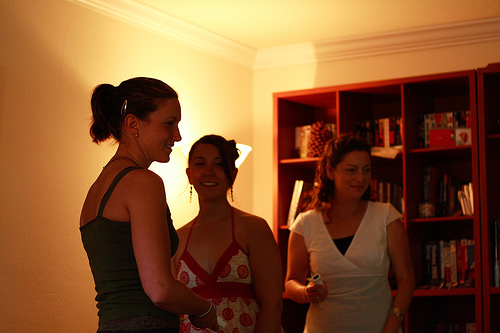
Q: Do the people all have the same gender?
A: Yes, all the people are female.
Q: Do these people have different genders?
A: No, all the people are female.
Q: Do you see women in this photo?
A: Yes, there are women.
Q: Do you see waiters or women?
A: Yes, there are women.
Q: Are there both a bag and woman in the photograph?
A: No, there are women but no bags.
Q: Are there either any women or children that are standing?
A: Yes, the women are standing.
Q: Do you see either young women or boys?
A: Yes, there are young women.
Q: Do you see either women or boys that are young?
A: Yes, the women are young.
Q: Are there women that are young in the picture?
A: Yes, there are young women.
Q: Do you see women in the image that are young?
A: Yes, there are women that are young.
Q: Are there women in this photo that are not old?
A: Yes, there are young women.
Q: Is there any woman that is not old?
A: Yes, there are young women.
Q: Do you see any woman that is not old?
A: Yes, there are young women.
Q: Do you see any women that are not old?
A: Yes, there are young women.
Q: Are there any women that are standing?
A: Yes, there are women that are standing.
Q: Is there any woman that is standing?
A: Yes, there are women that are standing.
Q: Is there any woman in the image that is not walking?
A: Yes, there are women that are standing.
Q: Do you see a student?
A: No, there are no students.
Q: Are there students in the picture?
A: No, there are no students.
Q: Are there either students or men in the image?
A: No, there are no students or men.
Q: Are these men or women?
A: These are women.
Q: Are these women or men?
A: These are women.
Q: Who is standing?
A: The women are standing.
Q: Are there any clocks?
A: No, there are no clocks.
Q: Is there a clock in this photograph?
A: No, there are no clocks.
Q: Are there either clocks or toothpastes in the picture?
A: No, there are no clocks or toothpastes.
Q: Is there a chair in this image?
A: No, there are no chairs.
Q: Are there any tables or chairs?
A: No, there are no chairs or tables.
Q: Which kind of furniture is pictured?
A: The furniture is a shelf.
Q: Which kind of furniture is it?
A: The piece of furniture is a shelf.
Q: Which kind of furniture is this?
A: This is a shelf.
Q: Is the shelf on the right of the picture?
A: Yes, the shelf is on the right of the image.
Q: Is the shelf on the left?
A: No, the shelf is on the right of the image.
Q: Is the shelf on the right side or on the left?
A: The shelf is on the right of the image.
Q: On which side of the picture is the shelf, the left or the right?
A: The shelf is on the right of the image.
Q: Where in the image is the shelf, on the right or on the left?
A: The shelf is on the right of the image.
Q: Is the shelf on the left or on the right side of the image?
A: The shelf is on the right of the image.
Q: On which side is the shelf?
A: The shelf is on the right of the image.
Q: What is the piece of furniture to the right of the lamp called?
A: The piece of furniture is a shelf.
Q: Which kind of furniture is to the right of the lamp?
A: The piece of furniture is a shelf.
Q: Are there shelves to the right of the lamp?
A: Yes, there is a shelf to the right of the lamp.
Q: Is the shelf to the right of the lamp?
A: Yes, the shelf is to the right of the lamp.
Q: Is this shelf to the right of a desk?
A: No, the shelf is to the right of the lamp.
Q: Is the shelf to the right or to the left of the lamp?
A: The shelf is to the right of the lamp.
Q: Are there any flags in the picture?
A: No, there are no flags.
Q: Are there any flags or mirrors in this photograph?
A: No, there are no flags or mirrors.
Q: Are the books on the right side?
A: Yes, the books are on the right of the image.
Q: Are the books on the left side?
A: No, the books are on the right of the image.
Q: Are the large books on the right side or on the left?
A: The books are on the right of the image.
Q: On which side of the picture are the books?
A: The books are on the right of the image.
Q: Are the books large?
A: Yes, the books are large.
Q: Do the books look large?
A: Yes, the books are large.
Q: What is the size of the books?
A: The books are large.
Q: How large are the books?
A: The books are large.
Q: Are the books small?
A: No, the books are large.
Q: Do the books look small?
A: No, the books are large.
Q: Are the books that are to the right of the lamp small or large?
A: The books are large.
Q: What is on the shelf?
A: The books are on the shelf.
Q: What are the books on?
A: The books are on the shelf.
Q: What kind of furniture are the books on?
A: The books are on the shelf.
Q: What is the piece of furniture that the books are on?
A: The piece of furniture is a shelf.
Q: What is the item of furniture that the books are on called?
A: The piece of furniture is a shelf.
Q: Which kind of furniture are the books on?
A: The books are on the shelf.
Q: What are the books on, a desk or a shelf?
A: The books are on a shelf.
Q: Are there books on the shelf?
A: Yes, there are books on the shelf.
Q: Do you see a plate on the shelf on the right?
A: No, there are books on the shelf.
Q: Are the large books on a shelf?
A: Yes, the books are on a shelf.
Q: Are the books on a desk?
A: No, the books are on a shelf.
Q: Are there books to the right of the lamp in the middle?
A: Yes, there are books to the right of the lamp.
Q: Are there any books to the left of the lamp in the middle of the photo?
A: No, the books are to the right of the lamp.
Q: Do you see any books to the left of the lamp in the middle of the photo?
A: No, the books are to the right of the lamp.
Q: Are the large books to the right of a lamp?
A: Yes, the books are to the right of a lamp.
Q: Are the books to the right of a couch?
A: No, the books are to the right of a lamp.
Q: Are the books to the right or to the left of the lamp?
A: The books are to the right of the lamp.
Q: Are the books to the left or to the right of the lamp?
A: The books are to the right of the lamp.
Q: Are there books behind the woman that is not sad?
A: Yes, there are books behind the woman.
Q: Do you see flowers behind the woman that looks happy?
A: No, there are books behind the woman.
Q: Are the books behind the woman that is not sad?
A: Yes, the books are behind the woman.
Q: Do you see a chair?
A: No, there are no chairs.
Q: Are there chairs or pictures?
A: No, there are no chairs or pictures.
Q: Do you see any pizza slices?
A: No, there are no pizza slices.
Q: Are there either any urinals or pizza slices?
A: No, there are no pizza slices or urinals.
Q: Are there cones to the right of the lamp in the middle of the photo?
A: Yes, there is a cone to the right of the lamp.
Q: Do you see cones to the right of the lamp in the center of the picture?
A: Yes, there is a cone to the right of the lamp.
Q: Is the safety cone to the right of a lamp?
A: Yes, the safety cone is to the right of a lamp.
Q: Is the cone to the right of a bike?
A: No, the cone is to the right of a lamp.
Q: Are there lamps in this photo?
A: Yes, there is a lamp.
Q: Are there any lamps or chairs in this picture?
A: Yes, there is a lamp.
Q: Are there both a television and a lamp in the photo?
A: No, there is a lamp but no televisions.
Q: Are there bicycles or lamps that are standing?
A: Yes, the lamp is standing.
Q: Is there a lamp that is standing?
A: Yes, there is a lamp that is standing.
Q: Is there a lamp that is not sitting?
A: Yes, there is a lamp that is standing.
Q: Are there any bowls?
A: No, there are no bowls.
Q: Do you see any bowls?
A: No, there are no bowls.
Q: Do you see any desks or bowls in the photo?
A: No, there are no bowls or desks.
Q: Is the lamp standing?
A: Yes, the lamp is standing.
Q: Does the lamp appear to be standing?
A: Yes, the lamp is standing.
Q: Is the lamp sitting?
A: No, the lamp is standing.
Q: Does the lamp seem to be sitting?
A: No, the lamp is standing.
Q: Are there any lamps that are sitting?
A: No, there is a lamp but it is standing.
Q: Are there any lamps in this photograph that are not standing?
A: No, there is a lamp but it is standing.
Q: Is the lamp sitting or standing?
A: The lamp is standing.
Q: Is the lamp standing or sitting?
A: The lamp is standing.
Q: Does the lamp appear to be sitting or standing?
A: The lamp is standing.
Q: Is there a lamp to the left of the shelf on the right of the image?
A: Yes, there is a lamp to the left of the shelf.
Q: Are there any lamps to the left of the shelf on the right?
A: Yes, there is a lamp to the left of the shelf.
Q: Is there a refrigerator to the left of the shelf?
A: No, there is a lamp to the left of the shelf.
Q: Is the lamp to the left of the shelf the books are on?
A: Yes, the lamp is to the left of the shelf.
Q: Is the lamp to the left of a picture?
A: No, the lamp is to the left of the shelf.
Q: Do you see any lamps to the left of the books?
A: Yes, there is a lamp to the left of the books.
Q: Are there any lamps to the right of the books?
A: No, the lamp is to the left of the books.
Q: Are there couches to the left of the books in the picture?
A: No, there is a lamp to the left of the books.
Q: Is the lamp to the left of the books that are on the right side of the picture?
A: Yes, the lamp is to the left of the books.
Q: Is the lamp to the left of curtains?
A: No, the lamp is to the left of the books.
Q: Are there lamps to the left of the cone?
A: Yes, there is a lamp to the left of the cone.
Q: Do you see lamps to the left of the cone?
A: Yes, there is a lamp to the left of the cone.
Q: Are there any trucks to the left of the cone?
A: No, there is a lamp to the left of the cone.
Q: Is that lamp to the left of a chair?
A: No, the lamp is to the left of a cone.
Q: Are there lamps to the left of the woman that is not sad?
A: Yes, there is a lamp to the left of the woman.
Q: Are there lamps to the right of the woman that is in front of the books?
A: No, the lamp is to the left of the woman.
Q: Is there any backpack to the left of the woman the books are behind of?
A: No, there is a lamp to the left of the woman.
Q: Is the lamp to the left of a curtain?
A: No, the lamp is to the left of the woman.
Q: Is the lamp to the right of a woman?
A: No, the lamp is to the left of a woman.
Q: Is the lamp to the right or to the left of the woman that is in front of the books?
A: The lamp is to the left of the woman.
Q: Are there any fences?
A: No, there are no fences.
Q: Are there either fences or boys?
A: No, there are no fences or boys.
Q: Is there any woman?
A: Yes, there is a woman.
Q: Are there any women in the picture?
A: Yes, there is a woman.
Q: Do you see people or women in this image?
A: Yes, there is a woman.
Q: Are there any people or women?
A: Yes, there is a woman.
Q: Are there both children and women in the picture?
A: No, there is a woman but no children.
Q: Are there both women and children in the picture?
A: No, there is a woman but no children.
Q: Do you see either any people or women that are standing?
A: Yes, the woman is standing.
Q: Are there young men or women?
A: Yes, there is a young woman.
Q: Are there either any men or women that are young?
A: Yes, the woman is young.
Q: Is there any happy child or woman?
A: Yes, there is a happy woman.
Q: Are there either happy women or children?
A: Yes, there is a happy woman.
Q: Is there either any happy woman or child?
A: Yes, there is a happy woman.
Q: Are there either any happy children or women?
A: Yes, there is a happy woman.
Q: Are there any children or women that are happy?
A: Yes, the woman is happy.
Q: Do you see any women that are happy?
A: Yes, there is a happy woman.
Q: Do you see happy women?
A: Yes, there is a happy woman.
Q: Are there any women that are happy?
A: Yes, there is a woman that is happy.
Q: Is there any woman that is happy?
A: Yes, there is a woman that is happy.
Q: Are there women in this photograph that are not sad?
A: Yes, there is a happy woman.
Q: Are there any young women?
A: Yes, there is a young woman.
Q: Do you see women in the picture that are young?
A: Yes, there is a woman that is young.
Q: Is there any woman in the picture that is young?
A: Yes, there is a woman that is young.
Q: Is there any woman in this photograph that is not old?
A: Yes, there is an young woman.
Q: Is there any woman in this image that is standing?
A: Yes, there is a woman that is standing.